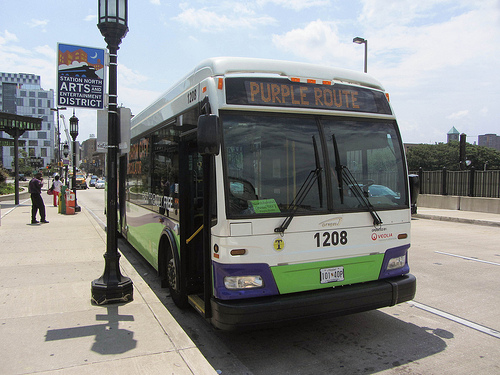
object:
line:
[405, 299, 500, 340]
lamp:
[97, 0, 130, 37]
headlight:
[387, 254, 407, 270]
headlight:
[223, 274, 265, 290]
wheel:
[166, 245, 189, 309]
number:
[314, 232, 321, 247]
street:
[71, 180, 498, 373]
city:
[2, 0, 494, 373]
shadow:
[43, 305, 137, 355]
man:
[28, 173, 49, 224]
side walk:
[2, 167, 179, 370]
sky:
[1, 2, 497, 142]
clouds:
[0, 0, 495, 143]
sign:
[56, 42, 108, 110]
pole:
[69, 108, 82, 212]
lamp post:
[90, 37, 133, 304]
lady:
[53, 175, 63, 207]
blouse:
[53, 180, 64, 192]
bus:
[104, 57, 416, 332]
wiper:
[273, 132, 382, 233]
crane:
[60, 113, 73, 148]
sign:
[244, 80, 379, 113]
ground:
[15, 190, 207, 370]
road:
[409, 202, 500, 371]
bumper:
[210, 273, 417, 331]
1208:
[314, 230, 348, 247]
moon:
[90, 51, 98, 59]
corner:
[90, 46, 107, 59]